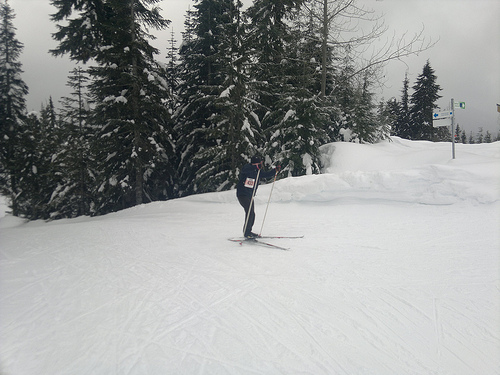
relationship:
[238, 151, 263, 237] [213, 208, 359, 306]
man on skis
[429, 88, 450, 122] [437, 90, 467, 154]
sign on pole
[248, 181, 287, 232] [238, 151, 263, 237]
poles with man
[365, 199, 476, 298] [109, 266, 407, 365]
snow on ground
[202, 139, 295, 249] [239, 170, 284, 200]
man has number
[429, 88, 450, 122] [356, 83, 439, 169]
sign for direction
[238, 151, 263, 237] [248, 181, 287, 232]
man has poles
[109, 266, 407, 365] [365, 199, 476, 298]
ground has snow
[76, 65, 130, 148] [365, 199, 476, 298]
leaves have snow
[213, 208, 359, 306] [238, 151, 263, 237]
skis on man